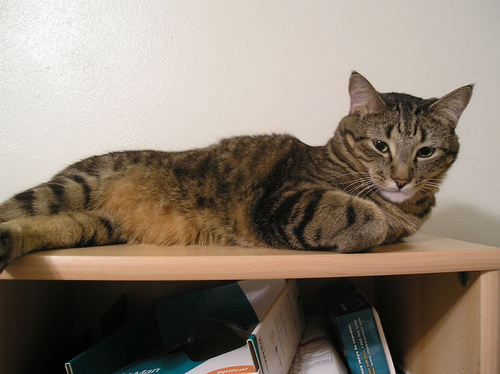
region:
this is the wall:
[146, 5, 193, 52]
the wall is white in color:
[126, 17, 268, 89]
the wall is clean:
[134, 3, 256, 110]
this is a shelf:
[153, 252, 210, 271]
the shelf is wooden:
[136, 250, 227, 272]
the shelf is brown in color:
[131, 255, 175, 270]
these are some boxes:
[141, 296, 389, 362]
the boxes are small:
[66, 283, 380, 358]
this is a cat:
[8, 64, 473, 245]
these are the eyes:
[361, 123, 450, 172]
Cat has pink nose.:
[389, 172, 419, 202]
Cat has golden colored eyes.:
[361, 126, 463, 163]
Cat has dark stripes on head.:
[393, 92, 440, 149]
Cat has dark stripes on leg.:
[273, 183, 345, 239]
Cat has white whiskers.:
[336, 172, 453, 196]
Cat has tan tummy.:
[128, 186, 203, 231]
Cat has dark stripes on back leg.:
[3, 177, 103, 207]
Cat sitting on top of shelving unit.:
[75, 99, 423, 229]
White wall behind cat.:
[93, 70, 213, 108]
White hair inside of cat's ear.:
[349, 75, 378, 115]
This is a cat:
[115, 126, 479, 286]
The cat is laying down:
[61, 120, 304, 280]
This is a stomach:
[155, 165, 245, 282]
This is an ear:
[275, 74, 368, 124]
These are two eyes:
[354, 133, 453, 155]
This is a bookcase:
[203, 226, 300, 344]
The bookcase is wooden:
[133, 245, 418, 356]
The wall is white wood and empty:
[185, 85, 202, 135]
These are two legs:
[15, 177, 112, 277]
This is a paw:
[284, 206, 451, 326]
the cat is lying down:
[10, 59, 474, 236]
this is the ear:
[345, 66, 388, 110]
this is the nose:
[393, 173, 411, 187]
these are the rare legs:
[0, 182, 90, 252]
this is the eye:
[368, 138, 389, 151]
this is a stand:
[413, 236, 479, 271]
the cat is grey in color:
[204, 152, 254, 203]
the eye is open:
[368, 136, 390, 156]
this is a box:
[180, 296, 303, 372]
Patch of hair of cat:
[29, 174, 66, 205]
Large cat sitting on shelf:
[5, 61, 446, 286]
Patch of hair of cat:
[85, 152, 127, 181]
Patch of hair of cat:
[129, 139, 164, 171]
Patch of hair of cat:
[90, 171, 152, 220]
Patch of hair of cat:
[170, 144, 252, 182]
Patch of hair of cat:
[245, 123, 300, 168]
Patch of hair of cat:
[305, 131, 348, 178]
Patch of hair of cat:
[318, 191, 364, 241]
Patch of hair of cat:
[256, 179, 336, 265]